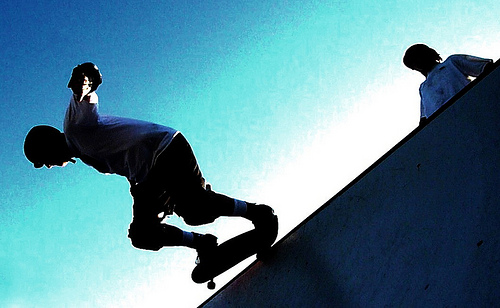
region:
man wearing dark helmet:
[25, 61, 277, 288]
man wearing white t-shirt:
[23, 60, 278, 293]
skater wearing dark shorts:
[23, 56, 280, 289]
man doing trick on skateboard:
[22, 61, 277, 289]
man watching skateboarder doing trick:
[400, 41, 492, 124]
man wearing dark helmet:
[400, 42, 489, 124]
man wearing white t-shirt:
[401, 42, 493, 122]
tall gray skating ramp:
[197, 60, 498, 305]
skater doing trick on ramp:
[23, 60, 280, 286]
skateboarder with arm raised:
[18, 61, 277, 290]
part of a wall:
[438, 174, 457, 190]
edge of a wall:
[359, 173, 378, 200]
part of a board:
[232, 241, 235, 246]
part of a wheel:
[211, 280, 217, 285]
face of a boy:
[426, 50, 434, 67]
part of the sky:
[245, 108, 266, 153]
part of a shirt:
[163, 134, 164, 143]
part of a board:
[208, 252, 212, 282]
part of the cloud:
[291, 128, 311, 190]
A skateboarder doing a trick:
[25, 62, 276, 291]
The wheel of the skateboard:
[204, 280, 219, 288]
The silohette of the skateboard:
[187, 222, 275, 290]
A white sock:
[227, 198, 250, 215]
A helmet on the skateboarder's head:
[22, 124, 62, 171]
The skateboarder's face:
[22, 126, 79, 168]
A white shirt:
[60, 93, 184, 183]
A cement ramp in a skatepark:
[200, 64, 499, 305]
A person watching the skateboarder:
[402, 42, 491, 119]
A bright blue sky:
[0, 1, 469, 306]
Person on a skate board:
[183, 211, 283, 288]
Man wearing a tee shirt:
[54, 108, 184, 156]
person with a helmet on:
[15, 127, 46, 158]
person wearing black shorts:
[103, 157, 217, 228]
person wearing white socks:
[229, 194, 253, 221]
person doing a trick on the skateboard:
[170, 230, 289, 265]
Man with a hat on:
[389, 43, 447, 69]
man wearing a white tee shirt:
[418, 78, 480, 105]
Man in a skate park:
[152, 214, 274, 262]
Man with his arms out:
[72, 60, 112, 139]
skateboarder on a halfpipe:
[17, 54, 290, 290]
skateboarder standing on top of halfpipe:
[398, 33, 498, 128]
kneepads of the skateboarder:
[127, 186, 220, 258]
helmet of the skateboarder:
[19, 124, 59, 166]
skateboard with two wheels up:
[188, 226, 274, 292]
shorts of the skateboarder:
[124, 135, 206, 218]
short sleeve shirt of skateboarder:
[75, 95, 167, 177]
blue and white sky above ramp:
[4, 15, 494, 305]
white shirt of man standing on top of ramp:
[416, 49, 478, 114]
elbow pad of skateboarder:
[63, 60, 103, 85]